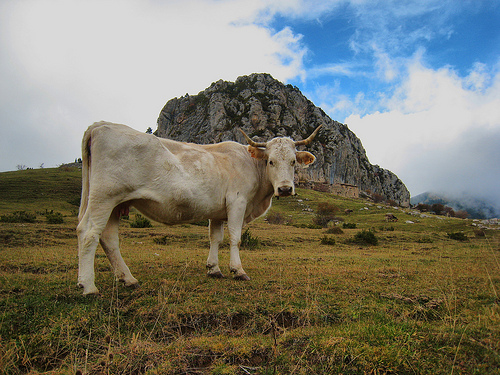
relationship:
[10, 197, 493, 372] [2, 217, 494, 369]
field has grass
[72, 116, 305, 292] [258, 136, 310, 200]
bull has face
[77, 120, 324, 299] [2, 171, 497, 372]
bull in field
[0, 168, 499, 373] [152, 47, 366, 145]
field has hill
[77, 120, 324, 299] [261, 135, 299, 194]
bull has head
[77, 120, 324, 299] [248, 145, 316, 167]
bull has ears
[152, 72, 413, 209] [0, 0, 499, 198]
hill set against sky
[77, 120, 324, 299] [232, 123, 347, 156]
bull has horns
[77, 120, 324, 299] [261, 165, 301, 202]
bull has nose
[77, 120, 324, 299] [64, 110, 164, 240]
bull has hind end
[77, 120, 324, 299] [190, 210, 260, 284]
bull has legs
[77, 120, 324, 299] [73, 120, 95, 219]
bull has tail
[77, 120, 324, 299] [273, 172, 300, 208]
bull has nose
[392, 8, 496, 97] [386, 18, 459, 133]
sky has clouds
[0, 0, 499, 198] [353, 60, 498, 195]
sky has cloud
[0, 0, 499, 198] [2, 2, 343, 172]
sky has cloud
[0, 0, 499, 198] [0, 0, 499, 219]
sky has cloud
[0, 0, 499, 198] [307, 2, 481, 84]
sky has cloud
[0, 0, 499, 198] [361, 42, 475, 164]
sky has cloud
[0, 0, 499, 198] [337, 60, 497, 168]
sky has cloud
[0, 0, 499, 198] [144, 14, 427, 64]
sky has clouds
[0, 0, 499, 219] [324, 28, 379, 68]
cloud in sky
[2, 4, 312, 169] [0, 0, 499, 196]
cloud in sky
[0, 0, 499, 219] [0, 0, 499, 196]
cloud in sky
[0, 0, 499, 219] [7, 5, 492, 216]
cloud in sky